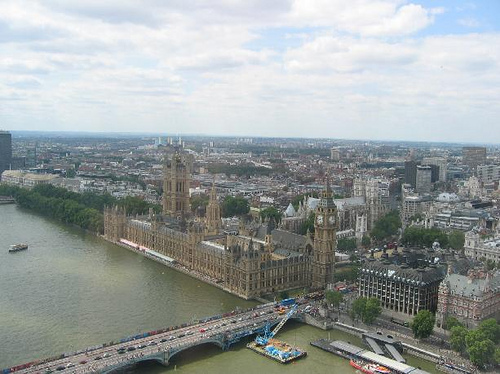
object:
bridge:
[0, 283, 358, 374]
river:
[0, 202, 454, 373]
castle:
[99, 151, 339, 300]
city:
[0, 128, 497, 374]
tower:
[161, 140, 190, 221]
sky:
[0, 0, 499, 145]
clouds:
[306, 5, 327, 17]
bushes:
[53, 199, 67, 206]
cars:
[230, 319, 237, 323]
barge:
[245, 301, 308, 365]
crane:
[262, 294, 308, 340]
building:
[309, 169, 340, 289]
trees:
[463, 328, 500, 372]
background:
[0, 130, 500, 304]